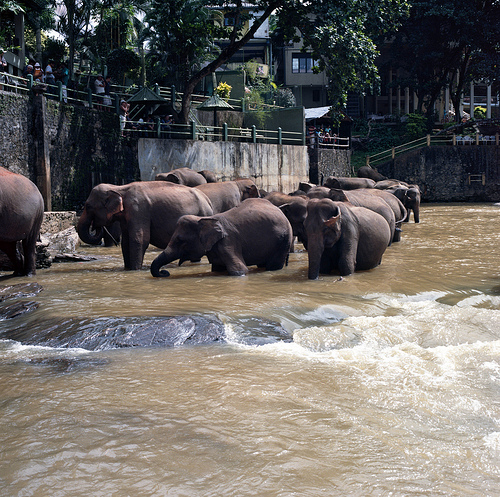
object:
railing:
[363, 128, 494, 167]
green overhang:
[3, 3, 277, 115]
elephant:
[293, 199, 388, 279]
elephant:
[73, 180, 212, 273]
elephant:
[384, 184, 421, 222]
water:
[0, 198, 500, 497]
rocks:
[76, 312, 232, 347]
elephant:
[151, 161, 212, 187]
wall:
[39, 206, 89, 271]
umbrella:
[128, 83, 235, 119]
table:
[240, 118, 262, 135]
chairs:
[167, 116, 191, 131]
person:
[47, 62, 80, 87]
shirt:
[90, 75, 105, 93]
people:
[44, 63, 58, 86]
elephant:
[0, 167, 45, 277]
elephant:
[190, 173, 265, 215]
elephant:
[308, 185, 397, 247]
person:
[311, 122, 341, 147]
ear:
[197, 212, 223, 251]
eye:
[180, 229, 194, 249]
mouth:
[176, 253, 190, 270]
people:
[26, 49, 158, 131]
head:
[149, 213, 209, 279]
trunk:
[147, 243, 181, 277]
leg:
[117, 224, 146, 272]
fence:
[0, 73, 302, 150]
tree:
[314, 22, 380, 138]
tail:
[385, 188, 410, 228]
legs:
[9, 234, 37, 278]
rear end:
[243, 198, 304, 252]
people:
[28, 57, 108, 109]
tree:
[401, 1, 491, 129]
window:
[293, 53, 316, 72]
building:
[200, 1, 329, 110]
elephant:
[144, 197, 292, 279]